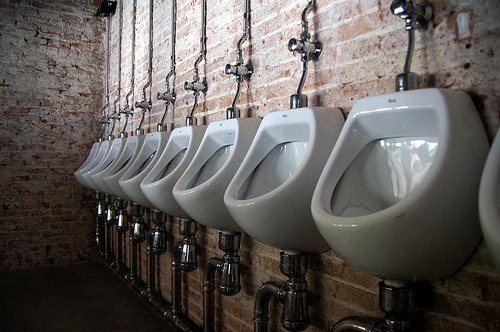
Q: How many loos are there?
A: 10.